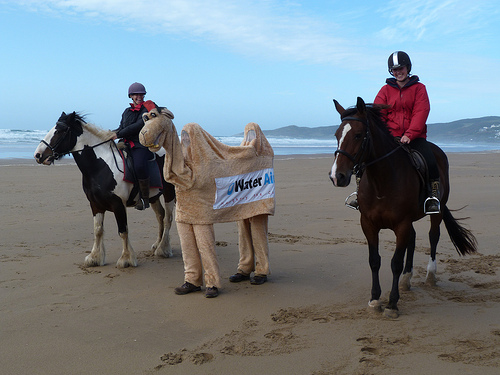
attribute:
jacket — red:
[369, 83, 443, 145]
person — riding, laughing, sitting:
[342, 48, 454, 217]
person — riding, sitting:
[104, 71, 172, 204]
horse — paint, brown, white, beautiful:
[29, 108, 189, 278]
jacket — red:
[362, 73, 431, 153]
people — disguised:
[136, 100, 291, 301]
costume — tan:
[136, 106, 291, 288]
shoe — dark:
[171, 273, 208, 298]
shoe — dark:
[200, 276, 225, 302]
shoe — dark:
[252, 260, 274, 288]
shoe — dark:
[221, 264, 254, 286]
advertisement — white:
[208, 162, 284, 216]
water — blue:
[1, 125, 500, 167]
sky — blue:
[0, 1, 498, 129]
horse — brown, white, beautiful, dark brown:
[322, 93, 474, 312]